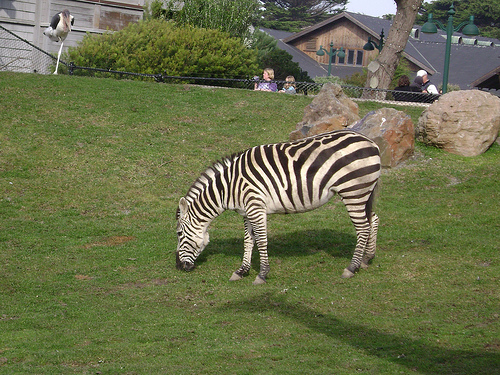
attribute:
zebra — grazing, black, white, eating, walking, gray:
[175, 127, 382, 286]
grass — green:
[0, 68, 498, 374]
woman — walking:
[250, 67, 279, 95]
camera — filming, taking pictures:
[250, 73, 259, 84]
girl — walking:
[280, 73, 298, 96]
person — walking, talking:
[392, 75, 411, 103]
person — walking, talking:
[412, 76, 429, 103]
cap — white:
[416, 67, 428, 78]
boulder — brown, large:
[286, 78, 360, 144]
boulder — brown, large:
[348, 105, 417, 171]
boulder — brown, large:
[412, 86, 499, 158]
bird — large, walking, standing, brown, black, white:
[41, 6, 77, 76]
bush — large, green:
[53, 18, 254, 90]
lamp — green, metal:
[420, 1, 482, 94]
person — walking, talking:
[416, 68, 438, 95]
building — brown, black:
[255, 9, 499, 107]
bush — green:
[147, 0, 276, 44]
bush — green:
[261, 47, 313, 89]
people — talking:
[392, 67, 441, 106]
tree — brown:
[360, 1, 426, 100]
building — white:
[3, 0, 185, 76]